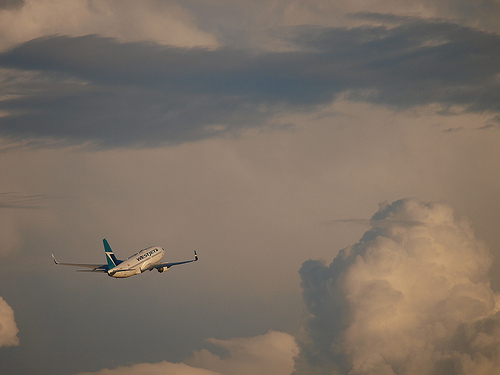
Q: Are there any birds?
A: No, there are no birds.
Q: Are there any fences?
A: No, there are no fences.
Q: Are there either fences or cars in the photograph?
A: No, there are no fences or cars.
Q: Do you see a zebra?
A: No, there are no zebras.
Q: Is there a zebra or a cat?
A: No, there are no zebras or cats.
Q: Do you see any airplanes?
A: Yes, there is an airplane.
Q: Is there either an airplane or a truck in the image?
A: Yes, there is an airplane.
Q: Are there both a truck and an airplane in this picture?
A: No, there is an airplane but no trucks.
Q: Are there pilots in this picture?
A: No, there are no pilots.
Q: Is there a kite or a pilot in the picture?
A: No, there are no pilots or kites.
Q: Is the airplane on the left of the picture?
A: Yes, the airplane is on the left of the image.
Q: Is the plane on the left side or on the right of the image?
A: The plane is on the left of the image.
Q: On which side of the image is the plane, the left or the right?
A: The plane is on the left of the image.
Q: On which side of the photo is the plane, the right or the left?
A: The plane is on the left of the image.